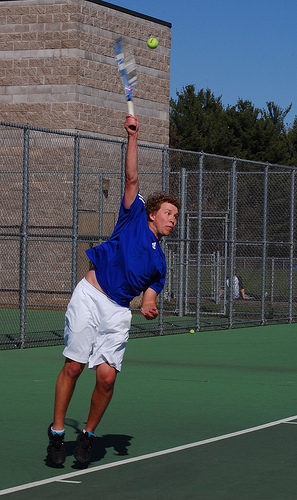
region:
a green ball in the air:
[141, 30, 166, 53]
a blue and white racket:
[109, 33, 145, 133]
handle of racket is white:
[126, 99, 138, 133]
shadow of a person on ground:
[47, 408, 135, 472]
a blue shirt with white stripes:
[90, 185, 170, 304]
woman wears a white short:
[45, 110, 188, 397]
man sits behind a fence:
[210, 262, 259, 308]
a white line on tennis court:
[0, 398, 296, 498]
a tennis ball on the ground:
[177, 317, 205, 341]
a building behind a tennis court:
[1, 15, 295, 368]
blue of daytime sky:
[102, 2, 295, 129]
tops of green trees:
[174, 85, 292, 161]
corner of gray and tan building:
[0, 43, 167, 301]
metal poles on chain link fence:
[1, 120, 294, 348]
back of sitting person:
[217, 265, 267, 301]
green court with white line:
[0, 324, 295, 497]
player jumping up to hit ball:
[47, 35, 201, 465]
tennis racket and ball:
[113, 34, 158, 130]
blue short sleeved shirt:
[85, 193, 165, 309]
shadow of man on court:
[44, 416, 133, 468]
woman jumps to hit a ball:
[30, 16, 202, 474]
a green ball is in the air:
[140, 31, 162, 58]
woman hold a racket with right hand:
[37, 29, 186, 473]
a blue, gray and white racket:
[109, 29, 151, 141]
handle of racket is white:
[118, 97, 143, 140]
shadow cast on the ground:
[41, 422, 143, 479]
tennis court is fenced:
[0, 118, 295, 434]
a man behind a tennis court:
[189, 172, 291, 367]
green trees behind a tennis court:
[173, 83, 295, 318]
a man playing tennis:
[44, 37, 179, 465]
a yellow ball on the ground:
[186, 327, 195, 333]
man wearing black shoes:
[43, 424, 94, 464]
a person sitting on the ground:
[217, 267, 267, 301]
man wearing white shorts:
[59, 277, 128, 372]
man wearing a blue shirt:
[84, 186, 166, 303]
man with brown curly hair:
[144, 190, 179, 237]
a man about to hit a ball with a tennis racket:
[42, 30, 178, 466]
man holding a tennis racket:
[113, 35, 137, 132]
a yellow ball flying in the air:
[146, 37, 157, 50]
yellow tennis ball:
[145, 35, 164, 51]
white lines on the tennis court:
[174, 434, 231, 445]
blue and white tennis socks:
[49, 424, 71, 434]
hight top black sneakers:
[49, 431, 73, 471]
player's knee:
[94, 372, 125, 393]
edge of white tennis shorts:
[85, 355, 150, 378]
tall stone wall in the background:
[24, 30, 91, 75]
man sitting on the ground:
[215, 258, 259, 307]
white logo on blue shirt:
[138, 236, 168, 256]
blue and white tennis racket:
[99, 29, 150, 117]